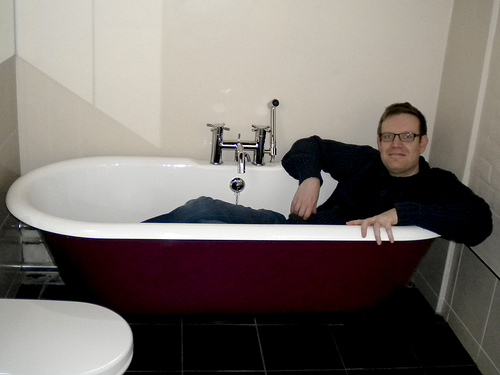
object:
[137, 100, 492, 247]
man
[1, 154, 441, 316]
tub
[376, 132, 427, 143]
glasses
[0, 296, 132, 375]
toilet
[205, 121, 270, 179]
faucet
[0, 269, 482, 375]
floor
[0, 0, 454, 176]
wall